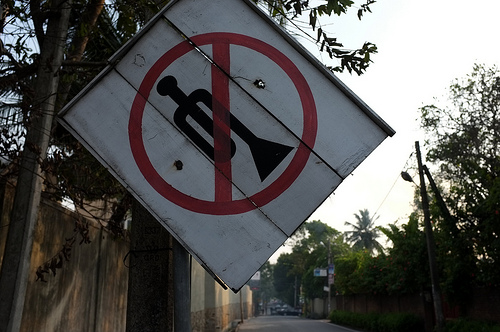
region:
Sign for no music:
[100, 10, 345, 242]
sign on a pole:
[309, 265, 332, 283]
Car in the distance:
[271, 302, 309, 322]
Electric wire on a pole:
[396, 138, 449, 330]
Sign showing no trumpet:
[69, 13, 351, 259]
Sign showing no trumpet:
[140, 30, 307, 200]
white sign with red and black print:
[59, 6, 393, 296]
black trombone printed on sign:
[152, 64, 288, 177]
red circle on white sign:
[127, 25, 313, 214]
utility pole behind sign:
[106, 22, 211, 331]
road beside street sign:
[230, 283, 359, 330]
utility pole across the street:
[407, 143, 452, 318]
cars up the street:
[265, 293, 297, 314]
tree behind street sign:
[8, 13, 339, 321]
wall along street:
[12, 204, 258, 331]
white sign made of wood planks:
[57, 15, 399, 272]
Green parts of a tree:
[465, 69, 499, 131]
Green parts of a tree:
[465, 133, 495, 192]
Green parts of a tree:
[413, 106, 463, 176]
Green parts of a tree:
[384, 217, 421, 275]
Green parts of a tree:
[341, 208, 383, 275]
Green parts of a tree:
[305, 224, 349, 262]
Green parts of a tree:
[274, 251, 310, 303]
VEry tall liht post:
[397, 135, 452, 326]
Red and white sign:
[90, 5, 335, 286]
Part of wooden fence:
[44, 203, 111, 330]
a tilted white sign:
[57, 0, 401, 293]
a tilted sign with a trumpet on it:
[55, 1, 399, 296]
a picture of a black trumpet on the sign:
[151, 72, 293, 182]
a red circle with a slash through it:
[127, 28, 318, 216]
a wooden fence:
[1, 169, 134, 329]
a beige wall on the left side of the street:
[189, 255, 256, 330]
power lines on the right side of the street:
[289, 143, 425, 329]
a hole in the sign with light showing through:
[249, 76, 266, 93]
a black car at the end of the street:
[270, 301, 304, 318]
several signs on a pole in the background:
[310, 262, 337, 284]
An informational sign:
[59, 2, 394, 297]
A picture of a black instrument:
[152, 72, 294, 184]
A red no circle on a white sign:
[128, 31, 325, 221]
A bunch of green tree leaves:
[318, 28, 385, 56]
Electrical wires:
[391, 152, 401, 212]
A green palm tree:
[338, 205, 389, 257]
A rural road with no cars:
[231, 308, 339, 330]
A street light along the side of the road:
[401, 141, 446, 328]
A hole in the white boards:
[248, 74, 272, 94]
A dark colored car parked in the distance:
[274, 305, 302, 317]